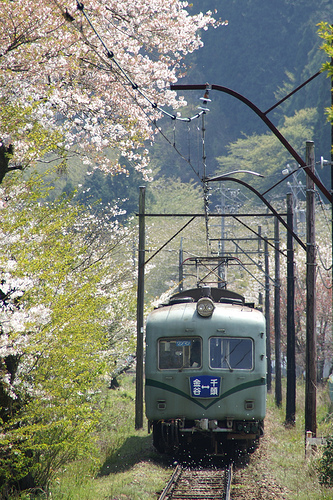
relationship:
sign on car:
[190, 374, 222, 397] [145, 287, 266, 462]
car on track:
[145, 287, 266, 462] [157, 454, 235, 498]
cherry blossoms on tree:
[1, 0, 223, 405] [12, 11, 204, 450]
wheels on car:
[153, 435, 256, 463] [144, 287, 265, 460]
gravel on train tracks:
[146, 403, 290, 498] [157, 449, 233, 498]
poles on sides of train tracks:
[99, 145, 320, 312] [154, 445, 233, 497]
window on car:
[157, 337, 202, 370] [145, 287, 266, 462]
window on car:
[208, 336, 252, 369] [145, 287, 266, 462]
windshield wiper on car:
[221, 354, 236, 373] [145, 287, 266, 462]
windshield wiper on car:
[177, 359, 193, 376] [145, 287, 266, 462]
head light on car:
[158, 401, 165, 409] [145, 287, 266, 462]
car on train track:
[145, 287, 266, 462] [153, 454, 238, 497]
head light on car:
[157, 400, 166, 408] [145, 287, 266, 462]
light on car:
[243, 399, 254, 412] [145, 287, 266, 462]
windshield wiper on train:
[223, 355, 233, 371] [111, 233, 292, 483]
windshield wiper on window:
[223, 355, 233, 371] [209, 336, 253, 369]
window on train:
[209, 336, 253, 369] [111, 233, 292, 483]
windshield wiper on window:
[178, 356, 193, 373] [157, 337, 202, 370]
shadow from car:
[96, 432, 154, 480] [145, 287, 266, 462]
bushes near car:
[0, 162, 129, 499] [145, 287, 266, 462]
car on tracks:
[145, 287, 266, 462] [76, 383, 257, 499]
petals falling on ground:
[153, 433, 264, 467] [116, 483, 305, 497]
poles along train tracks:
[163, 79, 327, 222] [149, 458, 239, 498]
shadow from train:
[93, 432, 153, 480] [131, 243, 298, 478]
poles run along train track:
[163, 79, 332, 204] [155, 457, 234, 498]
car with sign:
[145, 287, 266, 462] [190, 374, 222, 397]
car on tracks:
[145, 287, 266, 462] [158, 459, 237, 497]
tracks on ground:
[158, 459, 237, 497] [61, 254, 328, 497]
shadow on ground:
[93, 432, 153, 480] [257, 455, 299, 492]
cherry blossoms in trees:
[1, 2, 329, 456] [0, 0, 330, 482]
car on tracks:
[145, 287, 266, 462] [147, 435, 239, 498]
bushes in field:
[0, 196, 145, 475] [0, 328, 332, 495]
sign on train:
[187, 372, 222, 399] [137, 283, 271, 455]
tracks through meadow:
[157, 459, 233, 500] [45, 369, 321, 497]